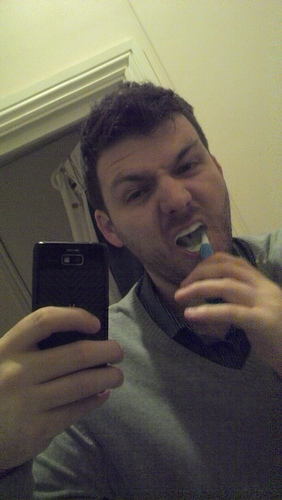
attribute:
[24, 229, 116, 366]
phone — black, motorola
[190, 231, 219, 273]
toothbrush — blue, plastic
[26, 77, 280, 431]
man — taking photo, white, brunette, ready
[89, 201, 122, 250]
ear — human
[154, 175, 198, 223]
nose — human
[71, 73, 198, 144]
hair — brown, curly, short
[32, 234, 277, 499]
sweater — grey, gray, v-neck, pullover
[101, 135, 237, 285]
face — angry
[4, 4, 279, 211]
wall — white, cream-colored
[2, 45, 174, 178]
door — wood